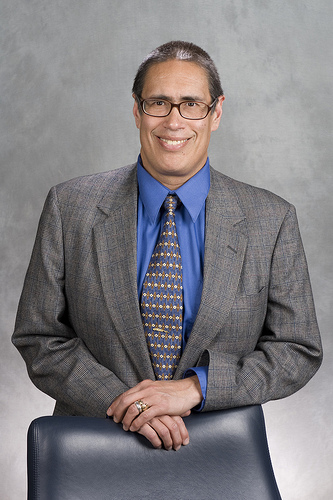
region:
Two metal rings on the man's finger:
[131, 398, 150, 413]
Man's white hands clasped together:
[106, 369, 206, 453]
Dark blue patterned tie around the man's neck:
[133, 193, 192, 387]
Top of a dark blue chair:
[22, 401, 286, 498]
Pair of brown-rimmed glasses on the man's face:
[128, 86, 218, 124]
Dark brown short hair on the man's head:
[120, 34, 229, 98]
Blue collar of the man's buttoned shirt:
[134, 161, 214, 225]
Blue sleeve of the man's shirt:
[181, 362, 214, 416]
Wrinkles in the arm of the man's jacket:
[6, 326, 96, 395]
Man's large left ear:
[210, 95, 226, 132]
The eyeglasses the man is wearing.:
[138, 95, 210, 118]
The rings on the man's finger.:
[134, 401, 148, 409]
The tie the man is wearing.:
[139, 190, 180, 382]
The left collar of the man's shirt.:
[145, 178, 163, 226]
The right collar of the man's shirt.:
[173, 188, 205, 226]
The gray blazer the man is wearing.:
[8, 163, 324, 425]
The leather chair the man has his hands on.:
[30, 404, 278, 497]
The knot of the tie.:
[161, 198, 176, 214]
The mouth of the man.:
[154, 134, 194, 148]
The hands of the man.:
[106, 373, 197, 452]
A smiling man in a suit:
[6, 13, 326, 490]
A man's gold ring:
[127, 396, 153, 414]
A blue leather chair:
[13, 398, 320, 498]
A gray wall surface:
[227, 7, 327, 165]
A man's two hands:
[98, 369, 213, 462]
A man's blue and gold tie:
[134, 188, 189, 384]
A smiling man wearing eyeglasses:
[69, 29, 279, 219]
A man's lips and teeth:
[147, 128, 202, 155]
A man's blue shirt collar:
[128, 154, 212, 229]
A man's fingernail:
[181, 432, 193, 448]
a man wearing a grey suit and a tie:
[9, 40, 327, 450]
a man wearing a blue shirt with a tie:
[116, 34, 232, 273]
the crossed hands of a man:
[108, 373, 204, 455]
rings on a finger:
[129, 398, 149, 413]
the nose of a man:
[161, 104, 186, 132]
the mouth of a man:
[150, 130, 191, 154]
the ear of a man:
[210, 94, 229, 133]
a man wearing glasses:
[129, 39, 229, 176]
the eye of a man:
[181, 99, 203, 111]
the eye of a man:
[149, 97, 170, 110]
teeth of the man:
[164, 138, 179, 144]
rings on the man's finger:
[135, 400, 144, 411]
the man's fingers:
[141, 423, 207, 452]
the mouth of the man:
[151, 131, 202, 151]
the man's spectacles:
[135, 95, 218, 121]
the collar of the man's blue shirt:
[177, 188, 207, 221]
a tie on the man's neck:
[145, 246, 180, 367]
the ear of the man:
[129, 93, 141, 128]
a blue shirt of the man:
[175, 183, 207, 298]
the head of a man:
[118, 35, 235, 171]